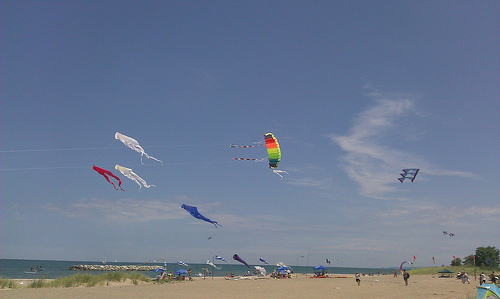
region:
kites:
[107, 102, 157, 222]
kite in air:
[247, 109, 305, 196]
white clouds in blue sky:
[378, 2, 433, 60]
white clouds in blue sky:
[420, 43, 444, 67]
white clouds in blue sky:
[315, 221, 359, 253]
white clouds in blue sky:
[331, 6, 369, 57]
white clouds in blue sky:
[180, 25, 212, 60]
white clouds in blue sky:
[24, 31, 114, 106]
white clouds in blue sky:
[24, 233, 64, 255]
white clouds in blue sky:
[132, 18, 199, 70]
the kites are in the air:
[66, 106, 429, 225]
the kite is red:
[90, 163, 108, 180]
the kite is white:
[111, 128, 150, 157]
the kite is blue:
[172, 200, 204, 220]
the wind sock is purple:
[230, 250, 250, 271]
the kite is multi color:
[261, 132, 281, 175]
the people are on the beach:
[346, 268, 482, 290]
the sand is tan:
[298, 280, 324, 294]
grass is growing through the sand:
[78, 273, 103, 290]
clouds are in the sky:
[355, 124, 381, 164]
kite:
[257, 111, 289, 169]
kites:
[75, 119, 209, 243]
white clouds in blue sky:
[325, 41, 389, 66]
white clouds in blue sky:
[345, 173, 360, 188]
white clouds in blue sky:
[342, 241, 369, 258]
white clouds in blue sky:
[352, 85, 387, 119]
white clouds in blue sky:
[305, 56, 339, 78]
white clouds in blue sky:
[194, 35, 229, 56]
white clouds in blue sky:
[167, 9, 234, 54]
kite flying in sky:
[397, 166, 422, 184]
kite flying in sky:
[228, 127, 296, 184]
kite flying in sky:
[176, 198, 225, 232]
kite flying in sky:
[112, 128, 155, 165]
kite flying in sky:
[113, 160, 153, 188]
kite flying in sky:
[89, 160, 126, 192]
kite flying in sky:
[408, 253, 420, 270]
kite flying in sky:
[428, 253, 439, 266]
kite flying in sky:
[230, 249, 249, 267]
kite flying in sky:
[203, 257, 222, 272]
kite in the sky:
[375, 150, 430, 186]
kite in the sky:
[235, 120, 315, 190]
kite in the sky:
[171, 190, 227, 226]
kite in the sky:
[106, 125, 161, 155]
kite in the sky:
[115, 155, 155, 181]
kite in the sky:
[85, 165, 120, 185]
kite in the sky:
[436, 225, 456, 240]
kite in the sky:
[225, 248, 250, 273]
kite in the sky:
[427, 253, 442, 269]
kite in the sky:
[390, 255, 410, 271]